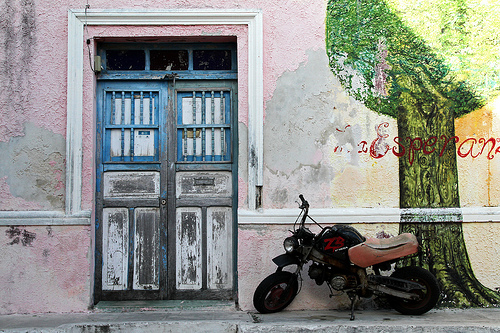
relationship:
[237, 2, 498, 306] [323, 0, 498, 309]
wall has green tree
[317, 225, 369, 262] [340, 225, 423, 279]
logo on motorcycle tank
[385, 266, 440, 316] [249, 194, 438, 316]
wheel of motorcycle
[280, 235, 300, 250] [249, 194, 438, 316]
headlight of motorcycle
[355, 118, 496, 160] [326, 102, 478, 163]
word in another language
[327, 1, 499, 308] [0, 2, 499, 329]
tree painted on building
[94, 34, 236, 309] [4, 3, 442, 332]
doors on building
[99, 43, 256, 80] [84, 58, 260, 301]
window above doors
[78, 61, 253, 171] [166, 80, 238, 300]
rails on door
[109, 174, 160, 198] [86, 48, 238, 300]
mail slot on door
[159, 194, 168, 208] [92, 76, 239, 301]
lock on door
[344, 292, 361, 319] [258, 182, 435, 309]
kick stand on dirt bike